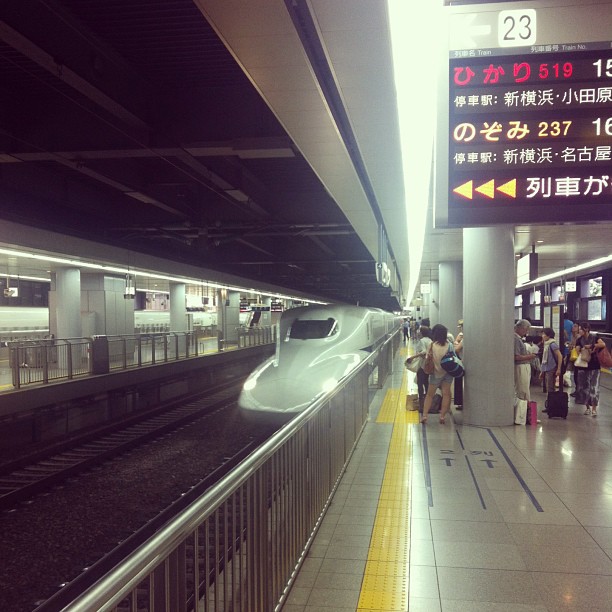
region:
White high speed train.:
[230, 301, 399, 432]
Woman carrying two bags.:
[416, 324, 464, 427]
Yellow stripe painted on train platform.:
[353, 327, 420, 611]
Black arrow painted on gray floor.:
[438, 454, 458, 468]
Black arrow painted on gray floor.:
[477, 456, 499, 468]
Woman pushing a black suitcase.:
[535, 327, 573, 421]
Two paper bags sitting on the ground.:
[512, 391, 540, 431]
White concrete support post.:
[50, 265, 83, 370]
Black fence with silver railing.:
[50, 320, 399, 607]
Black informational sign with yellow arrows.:
[445, 39, 610, 221]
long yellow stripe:
[349, 360, 416, 610]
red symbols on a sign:
[445, 54, 579, 90]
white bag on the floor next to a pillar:
[512, 395, 531, 431]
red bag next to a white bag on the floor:
[521, 395, 541, 432]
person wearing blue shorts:
[412, 322, 467, 432]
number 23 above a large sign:
[490, 5, 541, 53]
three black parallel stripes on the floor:
[413, 409, 549, 527]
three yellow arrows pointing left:
[449, 170, 522, 205]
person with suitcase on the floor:
[533, 321, 574, 427]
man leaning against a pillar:
[510, 315, 541, 405]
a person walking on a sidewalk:
[416, 322, 464, 425]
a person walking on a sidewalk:
[410, 322, 438, 416]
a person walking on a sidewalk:
[516, 321, 541, 416]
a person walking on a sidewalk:
[568, 323, 610, 417]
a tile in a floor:
[430, 511, 474, 550]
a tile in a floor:
[430, 534, 482, 569]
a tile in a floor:
[442, 564, 532, 603]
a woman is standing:
[419, 322, 455, 426]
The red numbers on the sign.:
[533, 61, 577, 81]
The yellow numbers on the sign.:
[538, 120, 571, 134]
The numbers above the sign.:
[498, 11, 531, 45]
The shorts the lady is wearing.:
[428, 369, 454, 384]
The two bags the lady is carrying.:
[422, 342, 467, 381]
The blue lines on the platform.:
[424, 413, 540, 520]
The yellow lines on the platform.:
[366, 342, 427, 610]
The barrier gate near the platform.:
[86, 288, 425, 612]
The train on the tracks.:
[239, 303, 387, 434]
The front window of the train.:
[293, 314, 335, 339]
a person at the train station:
[543, 332, 570, 423]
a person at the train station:
[426, 332, 460, 401]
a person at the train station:
[446, 315, 459, 385]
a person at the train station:
[518, 311, 530, 398]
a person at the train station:
[548, 325, 569, 415]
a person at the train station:
[548, 329, 577, 384]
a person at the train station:
[520, 316, 542, 403]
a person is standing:
[423, 326, 455, 422]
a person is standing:
[512, 320, 534, 406]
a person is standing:
[540, 325, 563, 394]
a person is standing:
[571, 324, 606, 410]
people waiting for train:
[401, 295, 610, 428]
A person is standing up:
[420, 321, 457, 427]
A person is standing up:
[535, 327, 565, 413]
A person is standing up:
[566, 323, 581, 365]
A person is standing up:
[509, 315, 530, 414]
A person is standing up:
[417, 321, 432, 392]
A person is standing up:
[453, 319, 467, 404]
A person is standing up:
[423, 314, 430, 334]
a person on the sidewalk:
[575, 317, 597, 450]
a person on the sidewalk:
[561, 302, 600, 423]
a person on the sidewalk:
[532, 313, 566, 406]